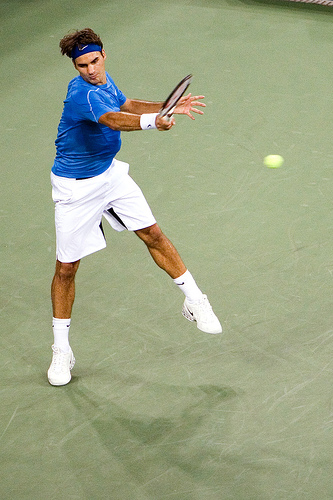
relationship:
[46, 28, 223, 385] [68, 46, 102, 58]
man wearing band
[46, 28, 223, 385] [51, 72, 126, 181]
man wearing shirt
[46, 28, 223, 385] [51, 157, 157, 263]
man wearing shorts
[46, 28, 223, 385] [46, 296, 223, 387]
man wearing shoe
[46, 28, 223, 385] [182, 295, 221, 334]
man with raised foot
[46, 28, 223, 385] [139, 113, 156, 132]
man wearing wrist band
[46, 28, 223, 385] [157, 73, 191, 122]
man swinging racket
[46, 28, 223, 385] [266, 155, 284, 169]
man hitting ball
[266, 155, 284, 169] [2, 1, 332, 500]
ball flying through air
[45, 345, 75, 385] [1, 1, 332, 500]
shoe on surface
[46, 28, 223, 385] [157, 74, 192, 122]
man playing tennis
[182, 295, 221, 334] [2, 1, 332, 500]
foot lifted in air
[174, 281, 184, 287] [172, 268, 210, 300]
logo on sock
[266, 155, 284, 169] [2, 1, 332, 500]
ball in air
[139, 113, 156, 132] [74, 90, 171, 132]
wrist band around arm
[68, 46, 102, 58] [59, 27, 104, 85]
band on head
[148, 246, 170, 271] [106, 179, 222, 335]
muscle on leg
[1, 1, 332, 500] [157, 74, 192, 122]
surface for playing tennis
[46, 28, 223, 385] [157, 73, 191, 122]
man holding racket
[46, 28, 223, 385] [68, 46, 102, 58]
man with band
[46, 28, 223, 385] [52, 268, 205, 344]
man wearing socks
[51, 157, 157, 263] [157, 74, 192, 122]
shorts are for tennis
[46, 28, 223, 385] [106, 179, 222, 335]
man has hairy leg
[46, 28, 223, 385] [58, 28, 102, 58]
man with hair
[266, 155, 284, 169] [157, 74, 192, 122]
ball for tennis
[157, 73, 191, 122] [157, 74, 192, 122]
racket for tennis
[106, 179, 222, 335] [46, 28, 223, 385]
leg of man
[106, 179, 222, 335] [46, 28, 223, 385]
leg of a man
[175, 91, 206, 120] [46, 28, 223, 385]
hand of a man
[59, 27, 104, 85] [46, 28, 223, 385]
head of a man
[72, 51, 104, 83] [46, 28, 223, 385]
face of a man